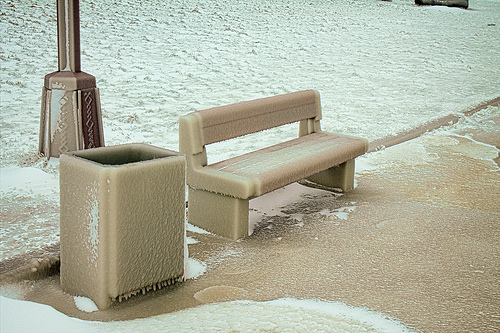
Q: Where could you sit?
A: Bench.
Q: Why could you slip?
A: Ice.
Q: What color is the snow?
A: White.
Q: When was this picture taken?
A: Daytime.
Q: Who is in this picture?
A: No one.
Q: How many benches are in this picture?
A: One.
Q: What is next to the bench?
A: Trash can.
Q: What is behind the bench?
A: Light pole.